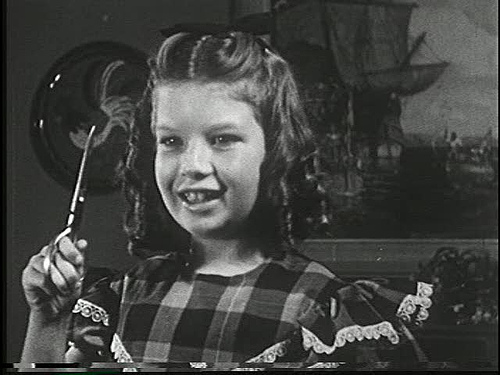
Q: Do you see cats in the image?
A: No, there are no cats.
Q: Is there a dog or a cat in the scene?
A: No, there are no cats or dogs.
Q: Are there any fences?
A: No, there are no fences.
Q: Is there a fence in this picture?
A: No, there are no fences.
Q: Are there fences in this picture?
A: No, there are no fences.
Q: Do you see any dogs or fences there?
A: No, there are no fences or dogs.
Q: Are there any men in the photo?
A: No, there are no men.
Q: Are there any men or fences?
A: No, there are no men or fences.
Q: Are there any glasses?
A: No, there are no glasses.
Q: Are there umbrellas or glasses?
A: No, there are no glasses or umbrellas.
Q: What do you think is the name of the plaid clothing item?
A: The clothing item is a dress.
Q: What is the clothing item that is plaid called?
A: The clothing item is a dress.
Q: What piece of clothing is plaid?
A: The clothing item is a dress.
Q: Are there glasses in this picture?
A: No, there are no glasses.